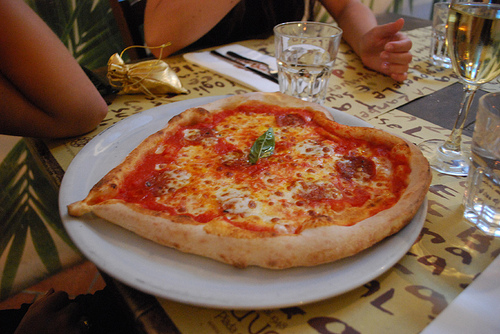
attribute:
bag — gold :
[103, 39, 187, 100]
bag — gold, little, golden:
[102, 35, 193, 103]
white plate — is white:
[58, 89, 430, 307]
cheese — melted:
[226, 184, 264, 216]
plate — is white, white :
[59, 94, 428, 311]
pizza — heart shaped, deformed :
[63, 87, 433, 274]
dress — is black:
[130, 0, 323, 62]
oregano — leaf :
[247, 120, 277, 165]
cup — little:
[269, 17, 341, 102]